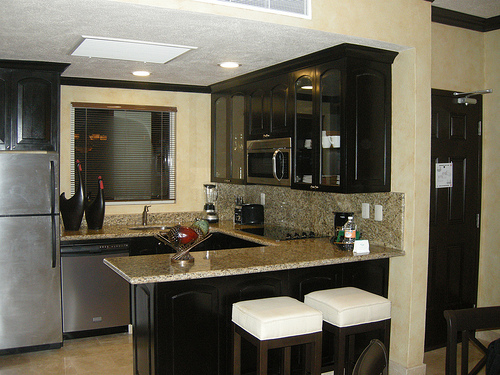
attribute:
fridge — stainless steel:
[3, 151, 62, 357]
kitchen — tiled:
[3, 0, 425, 370]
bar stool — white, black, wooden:
[231, 294, 326, 374]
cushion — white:
[230, 290, 321, 340]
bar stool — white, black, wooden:
[314, 285, 399, 374]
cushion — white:
[312, 280, 386, 330]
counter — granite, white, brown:
[65, 215, 402, 285]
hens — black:
[60, 148, 109, 232]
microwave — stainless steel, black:
[245, 140, 286, 186]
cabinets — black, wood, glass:
[202, 43, 390, 195]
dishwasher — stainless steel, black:
[60, 240, 132, 339]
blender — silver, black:
[199, 179, 222, 226]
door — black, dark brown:
[434, 89, 491, 356]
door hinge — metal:
[473, 122, 487, 231]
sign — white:
[433, 157, 455, 192]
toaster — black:
[234, 202, 260, 225]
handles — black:
[48, 159, 61, 268]